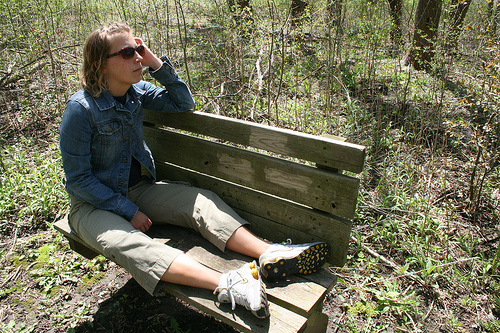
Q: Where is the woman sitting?
A: On a bench.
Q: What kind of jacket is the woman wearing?
A: Denim.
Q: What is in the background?
A: Trees.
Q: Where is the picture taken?
A: Park.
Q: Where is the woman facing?
A: Right.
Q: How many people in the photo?
A: 1.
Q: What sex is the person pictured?
A: Female.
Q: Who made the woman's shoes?
A: Nike.